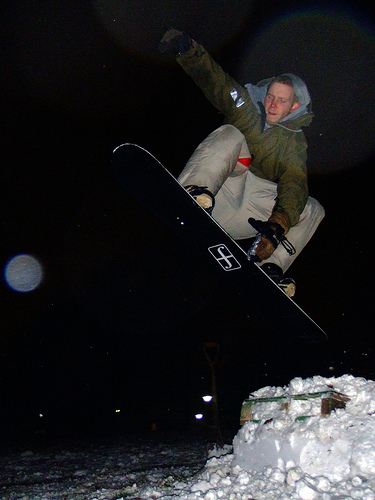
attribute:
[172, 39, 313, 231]
jacket — green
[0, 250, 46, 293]
moon — out of focus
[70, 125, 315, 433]
snow board — black